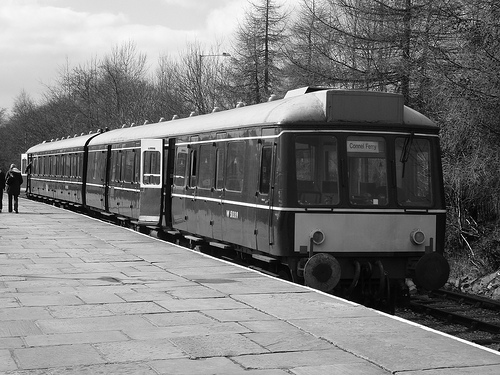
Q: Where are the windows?
A: On train.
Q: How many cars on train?
A: Two.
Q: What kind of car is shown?
A: Train.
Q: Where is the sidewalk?
A: Beside train.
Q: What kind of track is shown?
A: Railroad.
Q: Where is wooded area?
A: Behind train.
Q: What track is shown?
A: Train.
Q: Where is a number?
A: On train.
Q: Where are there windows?
A: Front and sides.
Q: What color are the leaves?
A: No leaves.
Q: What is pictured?
A: Train.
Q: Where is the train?
A: Station.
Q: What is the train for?
A: Transportation.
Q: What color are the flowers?
A: No flowers.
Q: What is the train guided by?
A: Tracks.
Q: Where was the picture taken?
A: At a train station.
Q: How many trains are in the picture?
A: 1.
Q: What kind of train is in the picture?
A: Passenger train.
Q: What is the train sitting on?
A: Tracks.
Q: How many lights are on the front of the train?
A: 2.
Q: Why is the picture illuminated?
A: Because it is daytime.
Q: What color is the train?
A: Grey.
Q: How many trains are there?
A: 1.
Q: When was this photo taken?
A: During the day.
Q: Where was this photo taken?
A: At a train station.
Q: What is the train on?
A: Tracks.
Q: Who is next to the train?
A: 2 people.